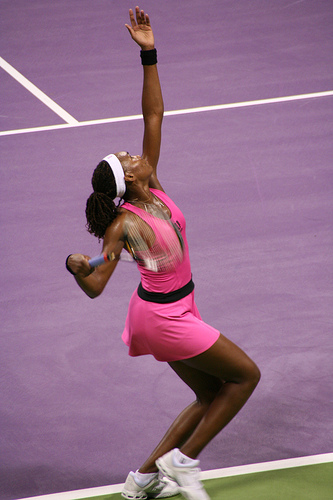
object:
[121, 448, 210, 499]
tennis shoes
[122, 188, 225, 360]
dress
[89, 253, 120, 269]
handle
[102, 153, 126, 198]
headband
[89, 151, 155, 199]
head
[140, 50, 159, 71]
wrist band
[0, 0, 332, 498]
court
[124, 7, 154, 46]
hand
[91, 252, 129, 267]
racket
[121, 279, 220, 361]
skirt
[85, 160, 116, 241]
hair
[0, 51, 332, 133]
stripes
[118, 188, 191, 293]
shirt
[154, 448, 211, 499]
shoe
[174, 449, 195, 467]
sock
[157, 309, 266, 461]
leg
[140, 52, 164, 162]
arm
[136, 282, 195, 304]
belt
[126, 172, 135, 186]
ear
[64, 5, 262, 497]
player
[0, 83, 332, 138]
line